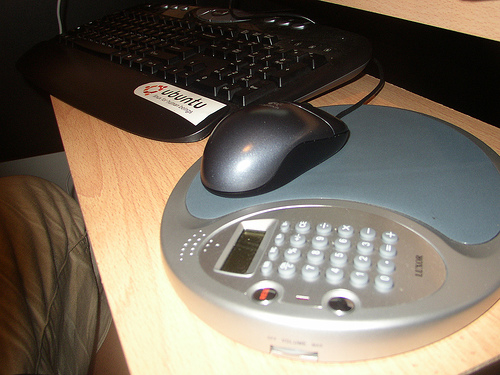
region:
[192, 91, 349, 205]
a grey and black computer mouse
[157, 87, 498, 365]
a computer mouse pad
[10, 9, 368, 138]
a black computer keyboard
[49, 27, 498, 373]
a brown keyboard desk shelf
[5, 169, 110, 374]
a pair of khaki pants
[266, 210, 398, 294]
a numeric key pad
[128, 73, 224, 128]
an operating system sticker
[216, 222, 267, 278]
a LED crystal display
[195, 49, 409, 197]
a corded mouse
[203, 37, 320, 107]
black keys with white caps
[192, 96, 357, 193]
silver and black mouse on desk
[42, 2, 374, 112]
black keyboard on a desk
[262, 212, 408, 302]
buttons on a calculator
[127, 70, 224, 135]
sticker on a keyboard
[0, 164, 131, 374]
leg of a person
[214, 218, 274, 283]
digital screen on a calculator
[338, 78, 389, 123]
black wire to a mouse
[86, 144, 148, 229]
wooden desk where keyboard is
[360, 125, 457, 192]
mouse pad on a calculator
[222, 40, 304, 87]
buttons on a keyboard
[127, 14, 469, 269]
a mouse on a mouse pad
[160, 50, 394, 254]
a computer mouse on mouse pad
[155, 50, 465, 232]
a black and silver mouse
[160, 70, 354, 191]
a black and silver computer mouse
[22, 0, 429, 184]
a keyboard with a sticker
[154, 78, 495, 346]
a mouse pad with a calculator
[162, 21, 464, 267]
a mouse pad on a desk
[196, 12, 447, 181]
a mouse with a cord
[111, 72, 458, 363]
a calculator mouse pad on table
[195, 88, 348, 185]
Blue and black wired computer mouse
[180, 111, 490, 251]
Blue and gray mouse pad with a mouse on it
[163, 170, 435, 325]
Gray calculator attached to a mousepad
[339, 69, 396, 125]
Black cable to a computer mouse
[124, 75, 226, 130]
Red and white sticker that says Ubuntu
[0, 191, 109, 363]
Tan colored shorts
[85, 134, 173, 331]
Wooden computer desk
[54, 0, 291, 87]
Black computer keyboard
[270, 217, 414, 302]
Soft keypad for a calcultator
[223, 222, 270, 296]
Calculator display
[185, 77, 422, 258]
the mouse is shiny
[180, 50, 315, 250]
the mouse is shiny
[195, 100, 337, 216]
the mouse is shiny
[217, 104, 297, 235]
the mouse is shiny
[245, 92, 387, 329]
the mouse is shiny